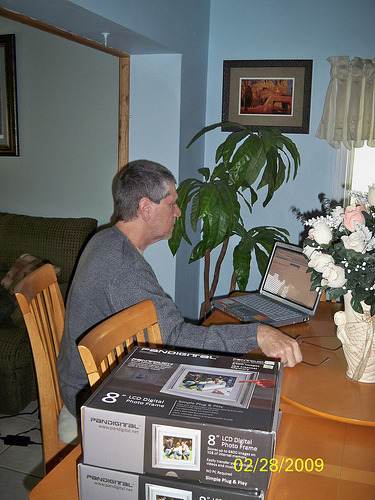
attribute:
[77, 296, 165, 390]
chair —  brown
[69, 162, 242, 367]
man — sitting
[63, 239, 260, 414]
sweatshirt — grey, crewneck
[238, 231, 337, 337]
laptop — silver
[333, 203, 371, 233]
flower — pink, rose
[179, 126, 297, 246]
houseplant — leafy, green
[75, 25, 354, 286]
wall — light blue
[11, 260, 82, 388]
chair — wooden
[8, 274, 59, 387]
chair — brown, wooden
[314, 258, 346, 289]
rose — white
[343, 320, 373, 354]
vase — white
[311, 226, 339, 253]
rose — white